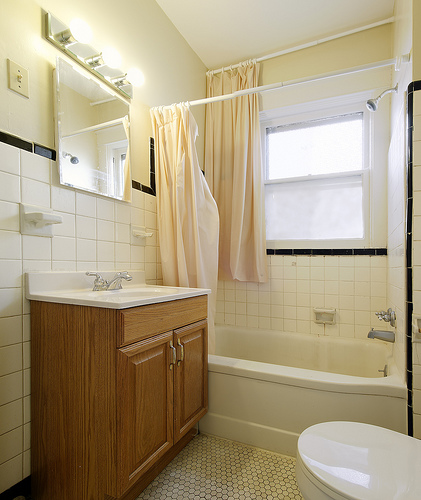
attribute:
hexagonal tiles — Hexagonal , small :
[138, 431, 299, 498]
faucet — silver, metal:
[84, 269, 132, 290]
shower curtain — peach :
[152, 110, 219, 291]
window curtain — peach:
[200, 67, 274, 289]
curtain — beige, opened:
[151, 94, 226, 287]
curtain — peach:
[199, 60, 271, 288]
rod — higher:
[141, 6, 393, 124]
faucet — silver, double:
[87, 267, 142, 299]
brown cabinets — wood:
[31, 293, 208, 498]